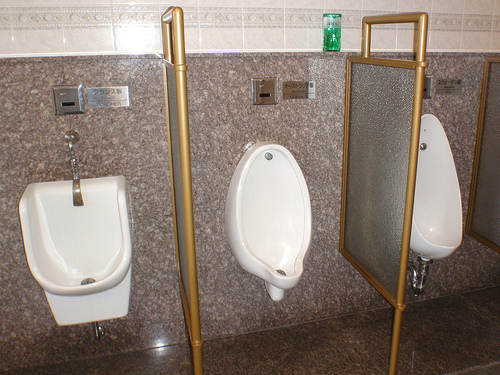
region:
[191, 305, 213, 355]
the cubicle line is yellow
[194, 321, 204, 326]
the cubicle line is yellow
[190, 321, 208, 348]
the cubicle line is yellow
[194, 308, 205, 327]
the cubicle line is yellow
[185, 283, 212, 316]
the cubicle line is yellow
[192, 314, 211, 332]
the cubicle line is yellow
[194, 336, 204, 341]
the cubicle line is yellow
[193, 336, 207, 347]
the cubicle line is yellow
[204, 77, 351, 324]
a white urinal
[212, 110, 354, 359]
a urinal on the wall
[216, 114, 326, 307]
a place where men pee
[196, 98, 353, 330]
a white toilet on wall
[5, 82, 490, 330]
three urinals on the wall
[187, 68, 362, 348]
a urinal inside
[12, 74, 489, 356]
three different urinals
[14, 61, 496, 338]
three white urinals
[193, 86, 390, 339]
urinal to pee in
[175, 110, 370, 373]
a clean urinal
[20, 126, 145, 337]
square urinal on left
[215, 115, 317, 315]
round urinal in the middle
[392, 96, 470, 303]
long urinal on the end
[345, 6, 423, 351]
gold pipes holding glass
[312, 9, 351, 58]
green air freshener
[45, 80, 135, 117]
metallic automatic flush mechanism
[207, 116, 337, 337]
granite walls behind urinal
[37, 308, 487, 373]
granite floors underneath urinals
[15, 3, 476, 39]
design on tile above urinals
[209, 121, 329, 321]
urinals are white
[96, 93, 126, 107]
japanese characters is written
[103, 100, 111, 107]
japanese characters is written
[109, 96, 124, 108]
japanese characters is written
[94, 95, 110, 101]
japanese characters is written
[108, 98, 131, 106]
japanese characters is written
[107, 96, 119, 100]
japanese characters is written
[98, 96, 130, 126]
japanese characters is written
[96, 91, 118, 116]
japanese characters is written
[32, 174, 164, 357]
the toilet is clean